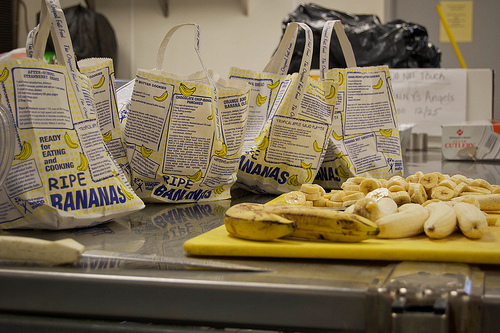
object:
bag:
[0, 56, 145, 229]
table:
[0, 144, 498, 332]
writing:
[50, 184, 127, 211]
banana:
[225, 202, 297, 241]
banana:
[451, 201, 487, 238]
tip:
[288, 219, 299, 232]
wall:
[18, 0, 383, 83]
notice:
[440, 0, 473, 44]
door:
[383, 0, 500, 126]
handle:
[24, 1, 77, 67]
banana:
[63, 131, 78, 148]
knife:
[1, 234, 275, 274]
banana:
[419, 173, 439, 187]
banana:
[422, 199, 458, 240]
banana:
[376, 202, 430, 241]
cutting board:
[184, 191, 499, 262]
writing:
[53, 12, 65, 40]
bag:
[270, 2, 443, 75]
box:
[440, 122, 499, 165]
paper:
[387, 68, 468, 135]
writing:
[391, 88, 457, 104]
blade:
[81, 249, 275, 275]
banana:
[264, 205, 380, 243]